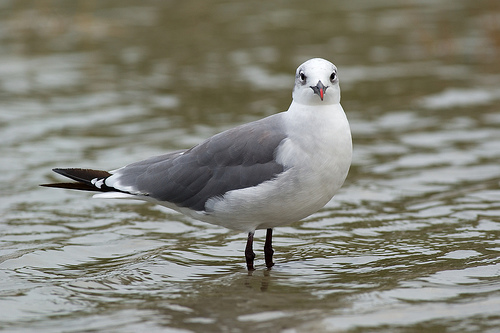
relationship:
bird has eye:
[37, 56, 354, 271] [299, 72, 306, 82]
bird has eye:
[37, 56, 354, 271] [330, 72, 335, 80]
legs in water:
[244, 227, 275, 272] [1, 0, 499, 333]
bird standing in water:
[37, 56, 354, 271] [1, 0, 499, 333]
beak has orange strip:
[319, 87, 324, 101] [319, 88, 324, 101]